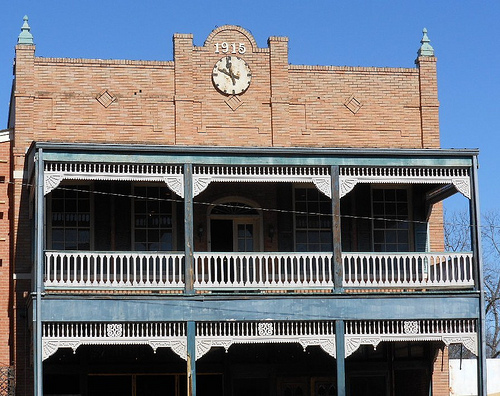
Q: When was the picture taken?
A: During the day.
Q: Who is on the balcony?
A: No one.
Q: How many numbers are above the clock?
A: Four.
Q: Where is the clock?
A: Beneath the address.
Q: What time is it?
A: 10:00.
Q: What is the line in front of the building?
A: Power line.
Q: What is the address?
A: 1915.